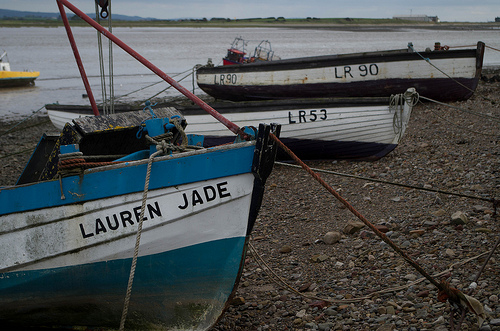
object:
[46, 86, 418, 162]
boats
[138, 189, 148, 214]
rope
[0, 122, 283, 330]
boat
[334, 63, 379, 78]
lr90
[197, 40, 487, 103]
boat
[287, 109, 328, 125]
lr 53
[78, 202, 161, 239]
lauren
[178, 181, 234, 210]
jade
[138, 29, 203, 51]
water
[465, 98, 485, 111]
rocks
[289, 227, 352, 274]
ground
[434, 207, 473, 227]
rock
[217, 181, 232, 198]
letters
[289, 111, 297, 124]
letter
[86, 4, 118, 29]
grommot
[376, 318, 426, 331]
land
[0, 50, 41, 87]
boat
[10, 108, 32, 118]
shore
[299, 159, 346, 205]
red rope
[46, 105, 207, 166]
rope holder